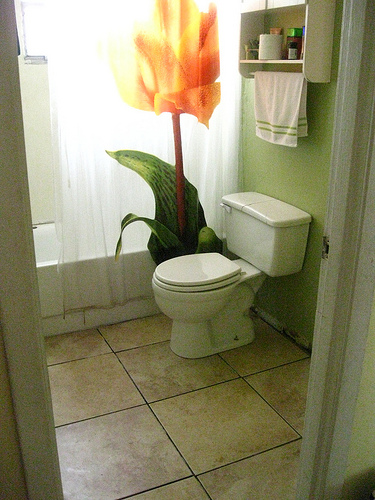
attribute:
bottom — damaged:
[248, 303, 311, 352]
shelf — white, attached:
[238, 9, 329, 77]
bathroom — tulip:
[3, 0, 345, 499]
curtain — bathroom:
[41, 1, 240, 317]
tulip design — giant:
[103, 1, 222, 268]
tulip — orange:
[103, 0, 221, 129]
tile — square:
[147, 371, 304, 477]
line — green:
[256, 118, 298, 129]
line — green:
[256, 123, 299, 135]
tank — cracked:
[210, 183, 317, 286]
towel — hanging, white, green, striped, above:
[251, 70, 314, 149]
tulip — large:
[102, 0, 223, 270]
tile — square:
[115, 342, 240, 403]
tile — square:
[218, 317, 309, 385]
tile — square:
[50, 351, 148, 429]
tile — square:
[56, 400, 197, 499]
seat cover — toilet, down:
[151, 251, 242, 284]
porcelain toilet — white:
[151, 193, 315, 358]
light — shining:
[36, 1, 82, 57]